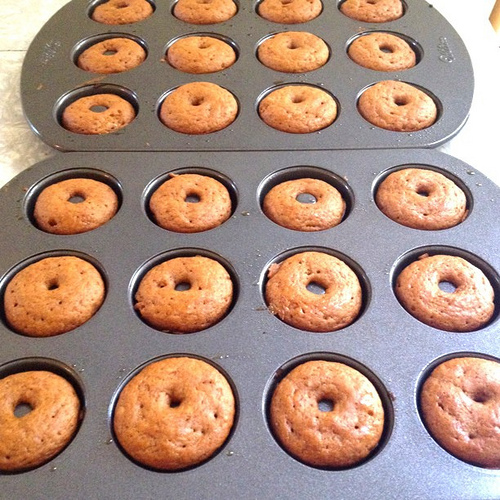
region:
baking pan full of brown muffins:
[10, 126, 490, 440]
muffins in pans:
[7, 11, 492, 481]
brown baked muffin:
[258, 252, 370, 328]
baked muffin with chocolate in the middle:
[122, 250, 250, 350]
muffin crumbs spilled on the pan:
[215, 180, 280, 330]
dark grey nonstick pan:
[32, 172, 478, 468]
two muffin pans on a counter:
[6, 11, 484, 482]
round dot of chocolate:
[291, 185, 331, 215]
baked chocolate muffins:
[45, 183, 477, 348]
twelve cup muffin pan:
[8, 150, 498, 457]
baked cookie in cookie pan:
[76, 30, 149, 72]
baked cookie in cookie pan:
[162, 34, 239, 76]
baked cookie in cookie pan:
[250, 29, 330, 67]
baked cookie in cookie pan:
[349, 30, 417, 65]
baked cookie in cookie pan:
[59, 85, 139, 132]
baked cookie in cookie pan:
[157, 83, 236, 130]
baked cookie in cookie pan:
[263, 343, 390, 475]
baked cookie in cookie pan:
[109, 343, 254, 475]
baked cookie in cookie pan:
[7, 249, 117, 336]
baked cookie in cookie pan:
[373, 153, 470, 232]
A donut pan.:
[3, 151, 498, 498]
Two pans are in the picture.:
[0, 0, 496, 496]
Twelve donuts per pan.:
[2, 165, 492, 485]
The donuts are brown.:
[5, 160, 495, 490]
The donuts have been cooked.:
[1, 155, 493, 490]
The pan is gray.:
[230, 325, 260, 375]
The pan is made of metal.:
[231, 316, 266, 362]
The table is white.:
[0, 67, 17, 158]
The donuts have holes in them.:
[120, 145, 382, 340]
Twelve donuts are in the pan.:
[6, 163, 493, 494]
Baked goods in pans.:
[21, 2, 496, 204]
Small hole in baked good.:
[162, 383, 190, 428]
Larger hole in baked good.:
[288, 379, 378, 439]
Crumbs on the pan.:
[98, 343, 225, 458]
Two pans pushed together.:
[48, 102, 494, 173]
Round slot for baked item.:
[240, 352, 472, 482]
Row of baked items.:
[21, 130, 486, 265]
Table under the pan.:
[11, 117, 64, 172]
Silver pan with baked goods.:
[70, 126, 368, 286]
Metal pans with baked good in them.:
[71, 132, 479, 337]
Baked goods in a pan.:
[33, 152, 491, 456]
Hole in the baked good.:
[250, 340, 393, 477]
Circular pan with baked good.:
[248, 316, 426, 489]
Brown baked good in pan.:
[123, 341, 258, 475]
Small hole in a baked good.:
[110, 350, 280, 477]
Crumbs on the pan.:
[207, 172, 304, 265]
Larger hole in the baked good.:
[286, 248, 355, 318]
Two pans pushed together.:
[21, 45, 458, 272]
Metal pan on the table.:
[207, 229, 424, 385]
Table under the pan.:
[17, 16, 201, 188]